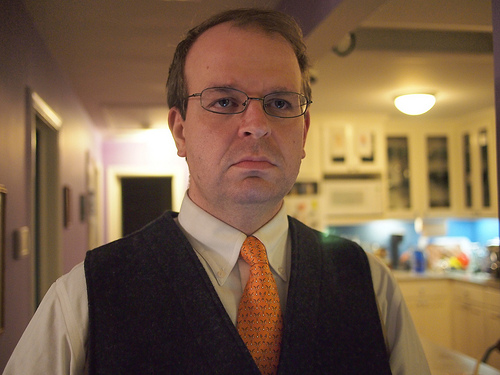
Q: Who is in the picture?
A: A man.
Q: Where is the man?
A: Dining room.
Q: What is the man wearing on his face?
A: Glasses.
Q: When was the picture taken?
A: Nighttime.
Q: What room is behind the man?
A: The kitchen.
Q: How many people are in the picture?
A: One.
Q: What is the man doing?
A: Looking.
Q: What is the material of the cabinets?
A: Wooden.